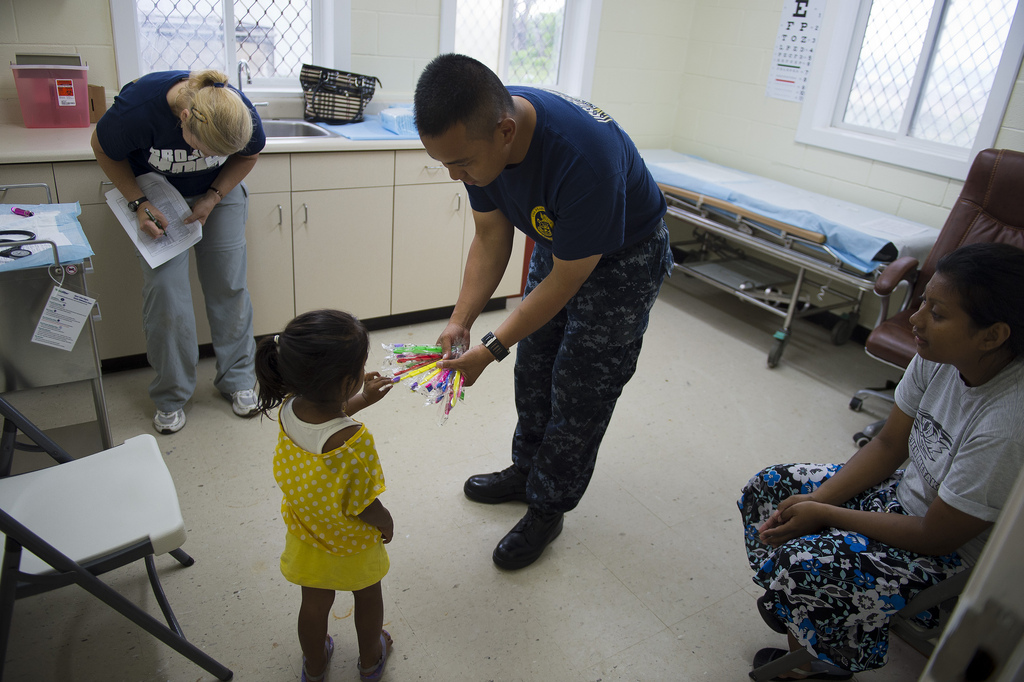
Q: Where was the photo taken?
A: In a doctors office.